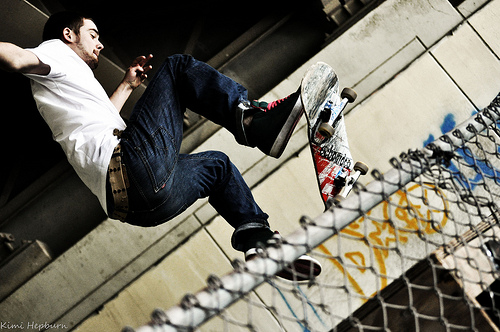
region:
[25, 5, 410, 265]
One boy is skating.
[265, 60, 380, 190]
skate board is white,red and black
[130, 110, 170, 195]
Boy is wearing blue jeans.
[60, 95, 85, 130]
Shirt is white color.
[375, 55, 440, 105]
wall is tan color.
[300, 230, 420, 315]
Fence is grey color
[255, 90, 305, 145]
Shoe is black in color.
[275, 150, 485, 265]
Letters are brown and blue color.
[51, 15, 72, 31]
Hair is black in color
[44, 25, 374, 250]
one man is doing tricks.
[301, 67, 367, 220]
One white skateboard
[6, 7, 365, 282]
Boy skateboarding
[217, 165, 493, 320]
Chain link fence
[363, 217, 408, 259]
Yellow spray painted star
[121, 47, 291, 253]
Boys blue jeans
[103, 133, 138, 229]
Beige belt holding the boy's pants up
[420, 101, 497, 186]
Blue graffiti painted on the wall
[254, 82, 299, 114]
Pink shoelaces in the boy's shoes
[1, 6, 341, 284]
Boy wearing a white shirt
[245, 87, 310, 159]
Boy's black shoes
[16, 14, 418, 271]
One boy is skating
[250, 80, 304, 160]
Shoe is black with red lace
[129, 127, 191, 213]
Boy is wearing blue pant.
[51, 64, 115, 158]
Shirt is white color.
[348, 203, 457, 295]
Fence is grey color.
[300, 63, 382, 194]
Skating board is white, red and black.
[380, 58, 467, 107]
Wall is brown in color.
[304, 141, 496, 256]
Letters in the wall are brown and blue.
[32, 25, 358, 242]
Boy is doing tricks.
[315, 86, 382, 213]
Four wheels in skating board.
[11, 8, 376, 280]
Man doing tricks on skateboard.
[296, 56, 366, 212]
Underside of white and red skateboard.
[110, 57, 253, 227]
Man wearing blue jeans.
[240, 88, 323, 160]
A black tennis shoe on man's foot.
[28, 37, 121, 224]
Man wearing white shirt.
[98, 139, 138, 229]
A tan belt around man's waist.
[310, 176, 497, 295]
Yellow graffiti on concrete wall.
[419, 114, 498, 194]
Blue graffiti on concrete wall.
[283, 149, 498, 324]
Chain link fence under skateboard.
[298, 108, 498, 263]
Metal pole supporting chain link fence.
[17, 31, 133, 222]
a white t-shirt on a young male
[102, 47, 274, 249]
blue jeans on a young male who is skating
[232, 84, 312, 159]
the right sneaker of a young skating male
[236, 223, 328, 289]
the left sneaker of a young skating male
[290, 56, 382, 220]
a skateboard being flipped mid-air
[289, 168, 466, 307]
yellow graffiti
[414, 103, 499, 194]
blue graffiti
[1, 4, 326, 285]
a young male skateboarding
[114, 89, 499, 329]
a chain link fence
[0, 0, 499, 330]
a large concrete structure in which a young male is skating on and near